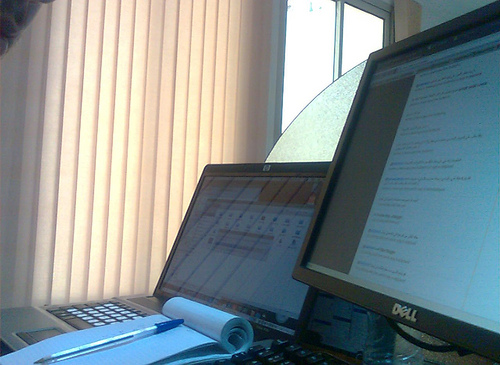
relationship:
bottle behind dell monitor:
[327, 297, 437, 348] [291, 0, 500, 365]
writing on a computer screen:
[342, 55, 496, 285] [279, 0, 497, 361]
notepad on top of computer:
[10, 293, 270, 363] [3, 161, 333, 361]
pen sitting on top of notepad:
[34, 317, 189, 364] [142, 328, 193, 355]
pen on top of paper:
[34, 317, 189, 364] [19, 297, 249, 362]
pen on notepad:
[34, 304, 189, 364] [2, 281, 255, 363]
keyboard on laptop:
[38, 296, 164, 333] [0, 161, 335, 363]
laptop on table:
[46, 131, 349, 357] [241, 98, 385, 358]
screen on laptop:
[158, 160, 334, 332] [0, 161, 335, 363]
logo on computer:
[390, 296, 425, 323] [308, 74, 499, 181]